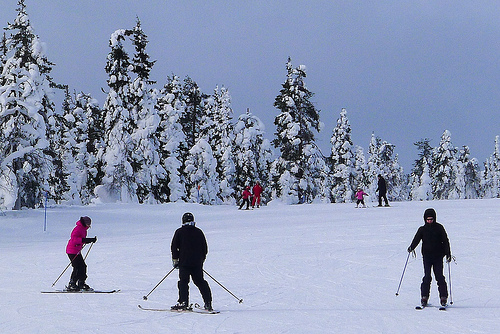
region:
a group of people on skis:
[47, 167, 461, 332]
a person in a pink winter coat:
[62, 216, 94, 251]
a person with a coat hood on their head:
[423, 207, 438, 229]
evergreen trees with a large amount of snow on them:
[98, 11, 236, 207]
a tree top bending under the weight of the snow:
[102, 16, 139, 61]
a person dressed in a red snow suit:
[247, 180, 264, 207]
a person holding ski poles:
[390, 243, 465, 305]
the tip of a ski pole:
[235, 290, 249, 301]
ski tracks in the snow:
[249, 231, 346, 299]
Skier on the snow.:
[389, 193, 468, 319]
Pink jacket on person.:
[59, 208, 97, 258]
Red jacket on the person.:
[250, 176, 266, 207]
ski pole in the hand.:
[192, 262, 247, 307]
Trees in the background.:
[0, 0, 496, 212]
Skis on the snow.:
[132, 300, 223, 316]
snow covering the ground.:
[0, 199, 498, 332]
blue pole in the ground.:
[37, 188, 52, 232]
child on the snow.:
[343, 180, 372, 207]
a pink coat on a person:
[64, 221, 85, 254]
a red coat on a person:
[252, 183, 265, 197]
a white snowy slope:
[0, 199, 497, 332]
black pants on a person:
[67, 252, 88, 289]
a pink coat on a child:
[354, 189, 367, 200]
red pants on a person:
[250, 195, 261, 206]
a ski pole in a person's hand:
[393, 251, 411, 297]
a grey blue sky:
[1, 1, 498, 174]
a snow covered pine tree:
[274, 57, 327, 203]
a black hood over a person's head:
[418, 206, 437, 228]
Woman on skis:
[41, 280, 121, 297]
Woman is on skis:
[35, 277, 126, 299]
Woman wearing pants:
[63, 247, 95, 290]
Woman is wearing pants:
[58, 248, 95, 286]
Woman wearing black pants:
[62, 250, 90, 285]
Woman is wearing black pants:
[68, 245, 89, 286]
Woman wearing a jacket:
[66, 218, 88, 256]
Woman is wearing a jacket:
[65, 217, 95, 256]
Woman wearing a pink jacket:
[65, 220, 92, 255]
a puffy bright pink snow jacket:
[65, 212, 95, 259]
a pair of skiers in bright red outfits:
[233, 178, 270, 212]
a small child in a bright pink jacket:
[350, 180, 377, 210]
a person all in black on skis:
[400, 195, 467, 315]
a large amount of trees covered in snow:
[6, 44, 494, 205]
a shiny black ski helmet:
[178, 206, 201, 226]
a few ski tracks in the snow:
[130, 309, 225, 332]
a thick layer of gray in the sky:
[343, 7, 470, 119]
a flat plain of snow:
[20, 187, 499, 307]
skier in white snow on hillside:
[48, 202, 115, 306]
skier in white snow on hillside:
[150, 207, 235, 314]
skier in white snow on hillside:
[398, 194, 460, 310]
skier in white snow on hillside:
[336, 174, 371, 220]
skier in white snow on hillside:
[364, 174, 391, 223]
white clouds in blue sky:
[175, 22, 197, 43]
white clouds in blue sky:
[349, 31, 382, 73]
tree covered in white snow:
[273, 69, 313, 168]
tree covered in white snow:
[321, 115, 368, 200]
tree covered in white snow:
[101, 35, 162, 144]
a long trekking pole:
[443, 255, 461, 292]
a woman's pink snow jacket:
[67, 217, 86, 256]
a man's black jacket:
[170, 220, 217, 266]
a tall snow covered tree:
[231, 111, 276, 208]